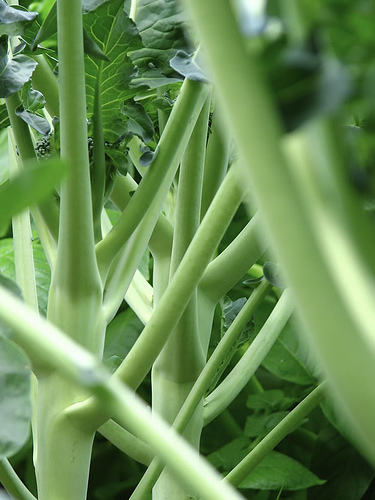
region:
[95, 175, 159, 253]
the long green stem of a plant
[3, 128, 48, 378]
the long green stem of a plant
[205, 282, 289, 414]
the long green stem of a plant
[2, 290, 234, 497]
the long green stem of a plant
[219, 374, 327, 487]
the long green stem of a plant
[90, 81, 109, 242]
the long green stem of a plant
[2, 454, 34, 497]
the long green stem of a plant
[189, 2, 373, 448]
the long green stem of a plant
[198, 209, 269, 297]
the long green stem of a plant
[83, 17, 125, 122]
veins in the leaf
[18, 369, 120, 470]
stem of the broccoli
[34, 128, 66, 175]
flower of the broccoli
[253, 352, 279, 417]
leaf of the broccoli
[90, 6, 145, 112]
green color leaf of the broccoli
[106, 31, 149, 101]
vein in the green color broccoli leaf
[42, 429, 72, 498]
light green color stem of the broccoli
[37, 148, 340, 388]
stem, leaf and flower of the plant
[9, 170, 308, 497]
broccoli plants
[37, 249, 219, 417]
two stem of the broccoli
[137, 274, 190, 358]
a green banana stem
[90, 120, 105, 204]
the flag leaf stem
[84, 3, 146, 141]
the banana trees flag leaf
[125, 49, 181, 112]
a wind torn banana flag leaf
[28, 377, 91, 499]
the pseudo stem of the banana tree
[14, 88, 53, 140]
a curled banana leaf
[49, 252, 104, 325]
a bent stem on the banana tree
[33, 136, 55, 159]
young banana tree buds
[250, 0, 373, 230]
thick forest of banana leaves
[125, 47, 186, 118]
wind blown banana flag leaf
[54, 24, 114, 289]
Small green stock on a plant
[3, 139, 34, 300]
Small green stock on a plant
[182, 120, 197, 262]
Small green stock on a plant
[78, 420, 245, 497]
Small green stock on a plant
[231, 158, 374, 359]
Small green stock on a plant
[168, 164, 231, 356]
Small green stock on a plant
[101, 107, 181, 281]
Small green stock on a plant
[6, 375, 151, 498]
Small green stock on a plant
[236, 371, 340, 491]
Small green stock on a plant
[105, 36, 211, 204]
Small green stock on a plant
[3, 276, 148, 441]
fresh green broccoli stem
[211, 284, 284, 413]
fresh green broccoli stem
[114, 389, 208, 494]
fresh green broccoli stem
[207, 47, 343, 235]
fresh green broccoli stem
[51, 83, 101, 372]
fresh green broccoli stem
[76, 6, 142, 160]
fresh green broccoli leaf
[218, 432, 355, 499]
fresh green broccoli leaf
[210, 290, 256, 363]
fresh green broccoli leaf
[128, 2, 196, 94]
fresh green broccoli leaf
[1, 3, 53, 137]
fresh green broccoli leaf